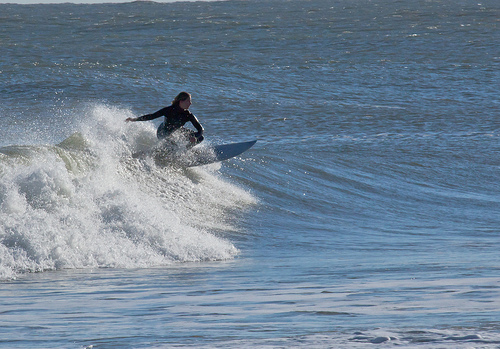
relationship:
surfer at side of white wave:
[113, 87, 233, 161] [1, 99, 239, 347]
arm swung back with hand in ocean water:
[117, 100, 165, 125] [4, 4, 500, 349]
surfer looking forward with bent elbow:
[121, 90, 206, 160] [188, 124, 209, 138]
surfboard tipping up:
[131, 136, 264, 175] [226, 124, 271, 168]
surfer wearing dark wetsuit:
[121, 90, 206, 160] [162, 105, 182, 137]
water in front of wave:
[22, 271, 498, 349] [23, 180, 245, 242]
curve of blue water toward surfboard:
[274, 96, 494, 233] [131, 136, 264, 175]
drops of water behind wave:
[2, 90, 90, 143] [82, 129, 107, 183]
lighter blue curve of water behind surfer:
[8, 50, 202, 96] [123, 99, 209, 180]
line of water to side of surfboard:
[261, 124, 481, 171] [131, 136, 264, 175]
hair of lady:
[174, 75, 188, 109] [123, 117, 227, 244]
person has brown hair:
[124, 90, 208, 155] [174, 99, 184, 103]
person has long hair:
[124, 90, 208, 155] [158, 97, 181, 102]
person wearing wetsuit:
[92, 61, 277, 230] [131, 104, 208, 158]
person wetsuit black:
[124, 90, 208, 155] [163, 108, 167, 129]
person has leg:
[124, 90, 208, 155] [177, 127, 207, 150]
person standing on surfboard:
[124, 90, 208, 155] [131, 136, 264, 175]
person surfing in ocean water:
[124, 90, 208, 155] [4, 4, 500, 349]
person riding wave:
[124, 90, 208, 155] [4, 122, 268, 273]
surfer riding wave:
[121, 90, 206, 160] [7, 127, 229, 270]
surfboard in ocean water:
[131, 136, 264, 175] [4, 4, 500, 349]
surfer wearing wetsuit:
[121, 90, 206, 160] [131, 104, 208, 158]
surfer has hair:
[121, 90, 206, 160] [166, 88, 190, 106]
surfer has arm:
[121, 90, 206, 160] [129, 104, 164, 125]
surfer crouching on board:
[121, 90, 206, 160] [129, 137, 259, 168]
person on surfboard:
[124, 90, 208, 155] [131, 136, 264, 175]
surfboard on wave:
[131, 136, 264, 175] [7, 127, 229, 270]